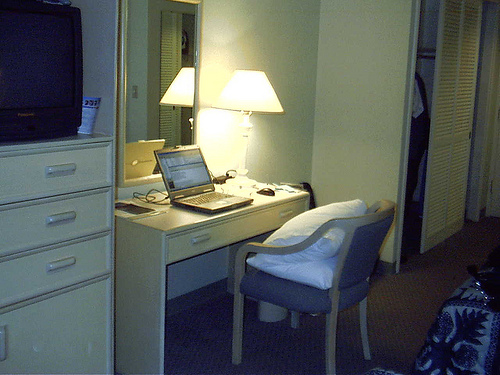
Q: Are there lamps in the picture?
A: Yes, there is a lamp.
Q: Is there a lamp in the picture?
A: Yes, there is a lamp.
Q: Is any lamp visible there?
A: Yes, there is a lamp.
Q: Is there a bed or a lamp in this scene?
A: Yes, there is a lamp.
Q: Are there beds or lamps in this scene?
A: Yes, there is a lamp.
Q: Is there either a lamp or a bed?
A: Yes, there is a lamp.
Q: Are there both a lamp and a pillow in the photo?
A: Yes, there are both a lamp and a pillow.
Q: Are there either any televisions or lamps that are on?
A: Yes, the lamp is on.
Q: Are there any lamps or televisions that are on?
A: Yes, the lamp is on.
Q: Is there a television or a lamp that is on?
A: Yes, the lamp is on.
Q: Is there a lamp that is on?
A: Yes, there is a lamp that is on.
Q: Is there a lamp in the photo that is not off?
A: Yes, there is a lamp that is on.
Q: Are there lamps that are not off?
A: Yes, there is a lamp that is on.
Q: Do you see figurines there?
A: No, there are no figurines.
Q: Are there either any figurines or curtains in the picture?
A: No, there are no figurines or curtains.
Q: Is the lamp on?
A: Yes, the lamp is on.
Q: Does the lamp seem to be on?
A: Yes, the lamp is on.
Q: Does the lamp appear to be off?
A: No, the lamp is on.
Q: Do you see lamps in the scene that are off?
A: No, there is a lamp but it is on.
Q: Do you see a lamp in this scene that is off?
A: No, there is a lamp but it is on.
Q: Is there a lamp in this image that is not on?
A: No, there is a lamp but it is on.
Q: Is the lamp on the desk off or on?
A: The lamp is on.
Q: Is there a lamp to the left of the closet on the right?
A: Yes, there is a lamp to the left of the closet.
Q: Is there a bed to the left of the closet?
A: No, there is a lamp to the left of the closet.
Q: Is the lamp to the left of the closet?
A: Yes, the lamp is to the left of the closet.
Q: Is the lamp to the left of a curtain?
A: No, the lamp is to the left of the closet.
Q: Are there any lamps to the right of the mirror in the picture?
A: Yes, there is a lamp to the right of the mirror.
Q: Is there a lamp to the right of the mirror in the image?
A: Yes, there is a lamp to the right of the mirror.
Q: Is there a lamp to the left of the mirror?
A: No, the lamp is to the right of the mirror.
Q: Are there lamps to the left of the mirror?
A: No, the lamp is to the right of the mirror.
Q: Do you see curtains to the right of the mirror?
A: No, there is a lamp to the right of the mirror.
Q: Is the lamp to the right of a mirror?
A: Yes, the lamp is to the right of a mirror.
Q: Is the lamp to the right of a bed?
A: No, the lamp is to the right of a mirror.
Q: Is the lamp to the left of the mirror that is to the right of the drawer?
A: No, the lamp is to the right of the mirror.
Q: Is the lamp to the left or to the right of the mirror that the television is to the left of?
A: The lamp is to the right of the mirror.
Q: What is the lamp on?
A: The lamp is on the desk.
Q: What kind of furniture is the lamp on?
A: The lamp is on the desk.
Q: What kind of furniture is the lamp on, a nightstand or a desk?
A: The lamp is on a desk.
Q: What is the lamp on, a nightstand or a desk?
A: The lamp is on a desk.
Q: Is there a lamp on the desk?
A: Yes, there is a lamp on the desk.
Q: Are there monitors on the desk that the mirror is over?
A: No, there is a lamp on the desk.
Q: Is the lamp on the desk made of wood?
A: Yes, the lamp is on the desk.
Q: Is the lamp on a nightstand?
A: No, the lamp is on the desk.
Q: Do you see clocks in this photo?
A: No, there are no clocks.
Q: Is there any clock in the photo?
A: No, there are no clocks.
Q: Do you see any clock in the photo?
A: No, there are no clocks.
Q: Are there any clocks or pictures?
A: No, there are no clocks or pictures.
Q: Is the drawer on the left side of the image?
A: Yes, the drawer is on the left of the image.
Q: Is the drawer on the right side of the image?
A: No, the drawer is on the left of the image.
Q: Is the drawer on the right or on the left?
A: The drawer is on the left of the image.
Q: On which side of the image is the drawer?
A: The drawer is on the left of the image.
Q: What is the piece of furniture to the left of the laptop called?
A: The piece of furniture is a drawer.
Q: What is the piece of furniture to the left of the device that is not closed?
A: The piece of furniture is a drawer.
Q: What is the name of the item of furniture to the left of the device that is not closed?
A: The piece of furniture is a drawer.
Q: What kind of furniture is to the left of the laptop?
A: The piece of furniture is a drawer.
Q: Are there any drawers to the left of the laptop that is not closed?
A: Yes, there is a drawer to the left of the laptop.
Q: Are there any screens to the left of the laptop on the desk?
A: No, there is a drawer to the left of the laptop.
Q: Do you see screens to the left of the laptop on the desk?
A: No, there is a drawer to the left of the laptop.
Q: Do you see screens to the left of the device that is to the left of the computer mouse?
A: No, there is a drawer to the left of the laptop.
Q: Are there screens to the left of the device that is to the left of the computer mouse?
A: No, there is a drawer to the left of the laptop.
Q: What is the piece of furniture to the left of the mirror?
A: The piece of furniture is a drawer.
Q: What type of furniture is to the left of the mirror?
A: The piece of furniture is a drawer.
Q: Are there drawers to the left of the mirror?
A: Yes, there is a drawer to the left of the mirror.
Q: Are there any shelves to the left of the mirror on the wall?
A: No, there is a drawer to the left of the mirror.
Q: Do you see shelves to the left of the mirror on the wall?
A: No, there is a drawer to the left of the mirror.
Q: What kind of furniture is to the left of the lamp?
A: The piece of furniture is a drawer.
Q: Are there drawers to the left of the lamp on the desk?
A: Yes, there is a drawer to the left of the lamp.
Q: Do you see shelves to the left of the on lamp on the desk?
A: No, there is a drawer to the left of the lamp.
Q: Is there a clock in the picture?
A: No, there are no clocks.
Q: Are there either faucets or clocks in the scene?
A: No, there are no clocks or faucets.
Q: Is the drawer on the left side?
A: Yes, the drawer is on the left of the image.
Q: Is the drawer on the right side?
A: No, the drawer is on the left of the image.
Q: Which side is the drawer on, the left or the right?
A: The drawer is on the left of the image.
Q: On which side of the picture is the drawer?
A: The drawer is on the left of the image.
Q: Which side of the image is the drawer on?
A: The drawer is on the left of the image.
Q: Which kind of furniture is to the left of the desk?
A: The piece of furniture is a drawer.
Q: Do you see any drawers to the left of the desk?
A: Yes, there is a drawer to the left of the desk.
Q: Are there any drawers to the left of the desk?
A: Yes, there is a drawer to the left of the desk.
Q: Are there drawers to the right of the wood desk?
A: No, the drawer is to the left of the desk.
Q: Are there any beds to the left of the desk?
A: No, there is a drawer to the left of the desk.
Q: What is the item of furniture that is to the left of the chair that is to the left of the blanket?
A: The piece of furniture is a drawer.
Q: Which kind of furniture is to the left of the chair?
A: The piece of furniture is a drawer.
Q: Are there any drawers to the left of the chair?
A: Yes, there is a drawer to the left of the chair.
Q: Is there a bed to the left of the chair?
A: No, there is a drawer to the left of the chair.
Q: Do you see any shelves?
A: No, there are no shelves.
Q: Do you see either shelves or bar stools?
A: No, there are no shelves or bar stools.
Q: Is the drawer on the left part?
A: Yes, the drawer is on the left of the image.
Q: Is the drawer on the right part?
A: No, the drawer is on the left of the image.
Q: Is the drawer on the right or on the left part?
A: The drawer is on the left of the image.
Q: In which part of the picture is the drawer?
A: The drawer is on the left of the image.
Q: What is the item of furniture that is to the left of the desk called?
A: The piece of furniture is a drawer.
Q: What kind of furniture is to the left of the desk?
A: The piece of furniture is a drawer.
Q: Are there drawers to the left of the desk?
A: Yes, there is a drawer to the left of the desk.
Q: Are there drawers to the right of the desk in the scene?
A: No, the drawer is to the left of the desk.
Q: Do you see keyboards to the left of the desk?
A: No, there is a drawer to the left of the desk.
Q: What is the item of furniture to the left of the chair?
A: The piece of furniture is a drawer.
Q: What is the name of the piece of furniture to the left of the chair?
A: The piece of furniture is a drawer.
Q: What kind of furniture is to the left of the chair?
A: The piece of furniture is a drawer.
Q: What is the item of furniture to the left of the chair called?
A: The piece of furniture is a drawer.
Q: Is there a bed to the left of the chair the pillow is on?
A: No, there is a drawer to the left of the chair.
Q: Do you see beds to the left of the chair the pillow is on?
A: No, there is a drawer to the left of the chair.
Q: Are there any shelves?
A: No, there are no shelves.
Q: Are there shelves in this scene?
A: No, there are no shelves.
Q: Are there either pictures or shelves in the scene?
A: No, there are no shelves or pictures.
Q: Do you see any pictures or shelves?
A: No, there are no shelves or pictures.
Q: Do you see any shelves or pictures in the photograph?
A: No, there are no shelves or pictures.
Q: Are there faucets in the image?
A: No, there are no faucets.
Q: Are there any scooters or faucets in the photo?
A: No, there are no faucets or scooters.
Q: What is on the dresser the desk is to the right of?
A: The paper is on the dresser.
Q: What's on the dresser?
A: The paper is on the dresser.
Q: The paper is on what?
A: The paper is on the dresser.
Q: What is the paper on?
A: The paper is on the dresser.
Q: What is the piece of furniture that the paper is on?
A: The piece of furniture is a dresser.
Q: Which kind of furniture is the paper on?
A: The paper is on the dresser.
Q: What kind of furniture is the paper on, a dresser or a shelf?
A: The paper is on a dresser.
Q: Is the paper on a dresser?
A: Yes, the paper is on a dresser.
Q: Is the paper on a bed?
A: No, the paper is on a dresser.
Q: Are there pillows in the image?
A: Yes, there is a pillow.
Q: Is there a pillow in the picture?
A: Yes, there is a pillow.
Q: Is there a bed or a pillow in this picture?
A: Yes, there is a pillow.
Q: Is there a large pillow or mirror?
A: Yes, there is a large pillow.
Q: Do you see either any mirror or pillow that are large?
A: Yes, the pillow is large.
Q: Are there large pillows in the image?
A: Yes, there is a large pillow.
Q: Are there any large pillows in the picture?
A: Yes, there is a large pillow.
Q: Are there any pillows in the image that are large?
A: Yes, there is a pillow that is large.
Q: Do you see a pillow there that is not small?
A: Yes, there is a large pillow.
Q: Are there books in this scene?
A: No, there are no books.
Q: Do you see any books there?
A: No, there are no books.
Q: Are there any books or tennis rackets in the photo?
A: No, there are no books or tennis rackets.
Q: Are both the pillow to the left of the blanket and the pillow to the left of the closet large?
A: Yes, both the pillow and the pillow are large.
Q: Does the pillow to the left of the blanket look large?
A: Yes, the pillow is large.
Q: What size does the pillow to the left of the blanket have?
A: The pillow has large size.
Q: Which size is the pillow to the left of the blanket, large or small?
A: The pillow is large.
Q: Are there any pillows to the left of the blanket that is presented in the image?
A: Yes, there is a pillow to the left of the blanket.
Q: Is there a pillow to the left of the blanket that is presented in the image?
A: Yes, there is a pillow to the left of the blanket.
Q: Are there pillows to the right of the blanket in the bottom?
A: No, the pillow is to the left of the blanket.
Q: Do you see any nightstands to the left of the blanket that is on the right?
A: No, there is a pillow to the left of the blanket.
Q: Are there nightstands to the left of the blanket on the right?
A: No, there is a pillow to the left of the blanket.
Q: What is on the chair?
A: The pillow is on the chair.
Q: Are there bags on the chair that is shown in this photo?
A: No, there is a pillow on the chair.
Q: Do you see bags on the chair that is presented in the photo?
A: No, there is a pillow on the chair.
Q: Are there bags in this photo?
A: No, there are no bags.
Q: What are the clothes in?
A: The clothes are in the closet.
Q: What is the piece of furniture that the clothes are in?
A: The piece of furniture is a closet.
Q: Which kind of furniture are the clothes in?
A: The clothes are in the closet.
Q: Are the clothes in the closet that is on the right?
A: Yes, the clothes are in the closet.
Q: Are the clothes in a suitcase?
A: No, the clothes are in the closet.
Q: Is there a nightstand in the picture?
A: No, there are no nightstands.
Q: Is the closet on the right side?
A: Yes, the closet is on the right of the image.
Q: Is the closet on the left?
A: No, the closet is on the right of the image.